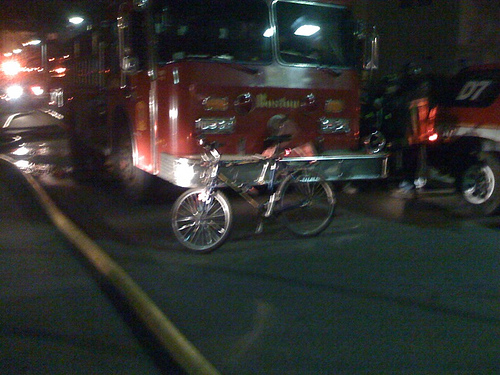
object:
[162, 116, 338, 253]
bicycle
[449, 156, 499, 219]
tire